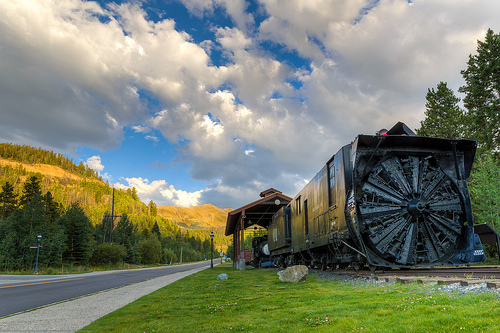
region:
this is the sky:
[116, 140, 171, 176]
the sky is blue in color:
[113, 153, 140, 172]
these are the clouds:
[253, 96, 335, 139]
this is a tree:
[465, 53, 498, 97]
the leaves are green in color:
[465, 67, 480, 81]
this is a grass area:
[163, 285, 248, 330]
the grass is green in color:
[210, 306, 301, 330]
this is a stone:
[279, 269, 301, 279]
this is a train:
[316, 158, 446, 252]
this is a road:
[17, 275, 60, 299]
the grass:
[258, 305, 273, 313]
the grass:
[247, 295, 280, 332]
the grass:
[254, 302, 274, 325]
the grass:
[277, 277, 312, 324]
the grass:
[296, 299, 323, 331]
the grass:
[247, 290, 310, 330]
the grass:
[283, 260, 334, 327]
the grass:
[227, 291, 259, 321]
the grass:
[291, 290, 343, 316]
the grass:
[307, 302, 331, 327]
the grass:
[256, 271, 328, 322]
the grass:
[287, 294, 318, 317]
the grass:
[240, 261, 298, 313]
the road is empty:
[4, 247, 214, 317]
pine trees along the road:
[0, 199, 205, 271]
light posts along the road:
[23, 222, 217, 274]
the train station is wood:
[217, 186, 290, 262]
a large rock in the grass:
[269, 259, 317, 299]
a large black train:
[264, 115, 482, 265]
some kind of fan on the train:
[348, 152, 466, 274]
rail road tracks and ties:
[412, 262, 497, 307]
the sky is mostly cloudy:
[5, 7, 454, 174]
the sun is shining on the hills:
[12, 144, 237, 234]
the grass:
[214, 283, 277, 331]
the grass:
[211, 231, 298, 321]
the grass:
[257, 296, 279, 313]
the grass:
[202, 254, 262, 327]